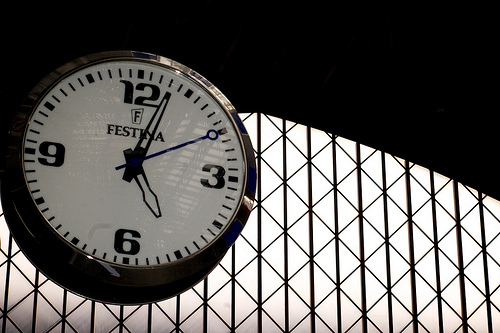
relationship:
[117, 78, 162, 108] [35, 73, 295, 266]
number on clock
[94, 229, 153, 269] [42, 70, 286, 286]
number on clock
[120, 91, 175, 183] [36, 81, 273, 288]
hand on clock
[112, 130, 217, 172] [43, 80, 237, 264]
hand on clock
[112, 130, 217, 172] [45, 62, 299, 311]
hand on clock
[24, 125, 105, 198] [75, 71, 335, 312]
number on clock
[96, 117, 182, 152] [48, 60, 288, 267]
word on clock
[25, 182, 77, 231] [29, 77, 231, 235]
lines on clock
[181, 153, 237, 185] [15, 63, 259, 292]
numbers on clock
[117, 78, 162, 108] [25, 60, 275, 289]
number on clock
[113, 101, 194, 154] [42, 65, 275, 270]
letters on clock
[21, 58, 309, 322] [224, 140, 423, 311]
clock on grate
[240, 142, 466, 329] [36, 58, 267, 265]
grate behind clock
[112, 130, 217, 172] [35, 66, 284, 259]
hand on clock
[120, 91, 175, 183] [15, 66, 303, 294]
hand on clock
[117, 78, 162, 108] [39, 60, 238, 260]
number on clock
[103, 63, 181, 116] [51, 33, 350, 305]
number on clock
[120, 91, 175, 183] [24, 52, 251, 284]
hand on clock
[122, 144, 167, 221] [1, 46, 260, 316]
hand on clock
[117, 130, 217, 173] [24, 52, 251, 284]
hand on clock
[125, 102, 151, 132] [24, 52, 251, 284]
letter on clock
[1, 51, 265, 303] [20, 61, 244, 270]
frame around clock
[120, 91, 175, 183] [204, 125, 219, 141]
hand has circle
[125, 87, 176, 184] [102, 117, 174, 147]
hand covering name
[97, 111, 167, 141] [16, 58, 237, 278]
name on clock face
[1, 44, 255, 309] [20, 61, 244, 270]
rim on clock